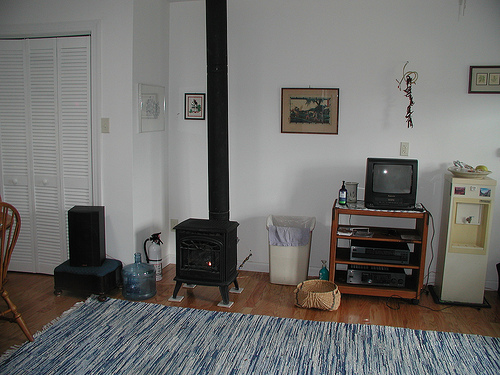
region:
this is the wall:
[266, 9, 318, 44]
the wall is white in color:
[306, 24, 358, 61]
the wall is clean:
[295, 13, 339, 51]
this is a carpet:
[71, 308, 138, 374]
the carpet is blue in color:
[84, 316, 119, 351]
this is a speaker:
[64, 202, 109, 265]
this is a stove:
[175, 227, 220, 279]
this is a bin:
[268, 221, 317, 287]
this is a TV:
[366, 153, 414, 203]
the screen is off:
[379, 166, 412, 197]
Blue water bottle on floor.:
[115, 251, 160, 301]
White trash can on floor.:
[263, 212, 312, 286]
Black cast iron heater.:
[168, 213, 243, 308]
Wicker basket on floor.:
[287, 275, 342, 312]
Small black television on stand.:
[364, 155, 424, 207]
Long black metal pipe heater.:
[206, 1, 231, 221]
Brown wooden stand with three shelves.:
[330, 196, 428, 306]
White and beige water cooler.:
[432, 174, 497, 311]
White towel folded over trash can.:
[267, 220, 310, 248]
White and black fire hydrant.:
[139, 232, 167, 282]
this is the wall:
[261, 4, 342, 54]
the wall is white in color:
[233, 188, 252, 209]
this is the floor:
[26, 295, 46, 315]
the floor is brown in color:
[18, 293, 41, 311]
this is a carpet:
[111, 312, 186, 373]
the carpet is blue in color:
[163, 312, 237, 355]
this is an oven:
[166, 218, 242, 306]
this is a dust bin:
[268, 221, 315, 283]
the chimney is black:
[198, 83, 234, 225]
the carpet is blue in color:
[103, 305, 252, 373]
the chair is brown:
[1, 199, 38, 329]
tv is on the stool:
[365, 155, 425, 210]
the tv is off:
[365, 157, 419, 207]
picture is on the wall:
[277, 85, 344, 143]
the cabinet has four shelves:
[333, 211, 433, 306]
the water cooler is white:
[443, 168, 483, 313]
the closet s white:
[6, 73, 83, 265]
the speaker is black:
[67, 203, 109, 265]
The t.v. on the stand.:
[365, 153, 417, 207]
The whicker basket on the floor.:
[293, 275, 343, 312]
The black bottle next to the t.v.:
[340, 180, 348, 206]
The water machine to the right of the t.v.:
[442, 163, 489, 305]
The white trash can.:
[262, 211, 312, 286]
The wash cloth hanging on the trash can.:
[267, 226, 307, 246]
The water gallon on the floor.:
[127, 253, 154, 302]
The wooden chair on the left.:
[2, 202, 32, 338]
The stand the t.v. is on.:
[328, 193, 425, 306]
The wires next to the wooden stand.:
[416, 205, 444, 310]